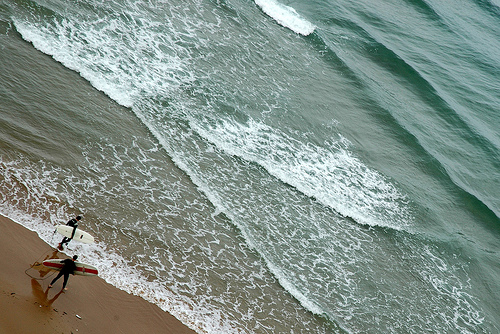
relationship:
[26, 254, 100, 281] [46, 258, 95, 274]
surfboard has stripe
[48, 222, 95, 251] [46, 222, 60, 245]
board has tether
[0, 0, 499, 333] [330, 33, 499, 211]
ripple in water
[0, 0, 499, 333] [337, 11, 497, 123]
ripple in water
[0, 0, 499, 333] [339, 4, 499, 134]
ripple in water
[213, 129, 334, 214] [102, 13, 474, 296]
ripple in water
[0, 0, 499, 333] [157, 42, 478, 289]
ripple in water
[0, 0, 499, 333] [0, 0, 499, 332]
ripple in sea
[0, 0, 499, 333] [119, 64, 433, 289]
ripple in water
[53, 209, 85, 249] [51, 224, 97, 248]
person carrying surfboard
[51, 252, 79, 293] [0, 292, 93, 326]
person on sand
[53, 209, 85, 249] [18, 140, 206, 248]
person in water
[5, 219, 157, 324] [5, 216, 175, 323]
area of sand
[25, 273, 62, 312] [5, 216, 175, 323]
reflection on sand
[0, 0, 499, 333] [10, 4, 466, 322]
ripple in water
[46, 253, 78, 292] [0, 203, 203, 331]
person at beach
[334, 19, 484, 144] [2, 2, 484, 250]
tides on sea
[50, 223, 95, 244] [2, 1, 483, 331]
board in photo